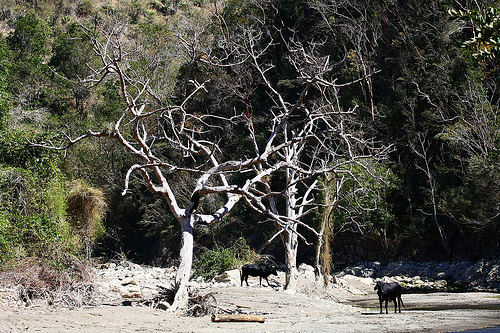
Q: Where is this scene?
A: Forest.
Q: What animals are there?
A: Cows.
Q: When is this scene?
A: Afternoon.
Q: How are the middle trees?
A: Gnarled.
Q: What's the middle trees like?
A: Leafless.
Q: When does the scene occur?
A: Daytime.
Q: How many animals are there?
A: Two.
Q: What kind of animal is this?
A: A cow.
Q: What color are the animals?
A: Black.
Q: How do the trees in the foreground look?
A: The branches are bare.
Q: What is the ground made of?
A: Dry dirt.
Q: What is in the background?
A: A dense forest.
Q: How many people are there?
A: None.